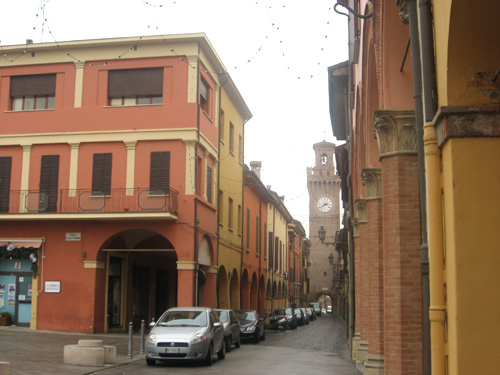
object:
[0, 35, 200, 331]
building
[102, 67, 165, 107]
window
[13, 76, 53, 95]
shade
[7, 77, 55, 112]
window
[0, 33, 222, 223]
trim